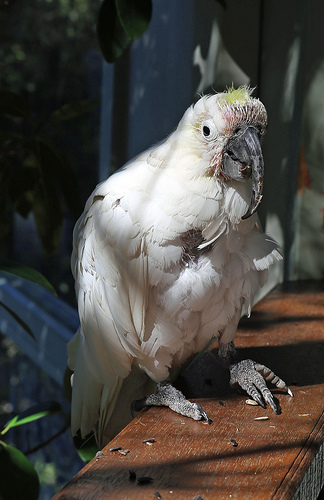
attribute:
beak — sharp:
[220, 128, 266, 220]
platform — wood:
[49, 279, 323, 499]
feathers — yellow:
[217, 82, 250, 108]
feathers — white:
[55, 29, 303, 433]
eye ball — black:
[201, 125, 213, 139]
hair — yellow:
[221, 80, 246, 104]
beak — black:
[224, 126, 268, 219]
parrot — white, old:
[55, 81, 299, 454]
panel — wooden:
[62, 389, 319, 499]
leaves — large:
[1, 0, 155, 256]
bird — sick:
[63, 79, 294, 451]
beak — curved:
[237, 127, 265, 218]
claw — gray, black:
[237, 375, 265, 406]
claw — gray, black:
[250, 369, 278, 412]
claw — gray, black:
[251, 361, 294, 396]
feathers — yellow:
[196, 68, 275, 175]